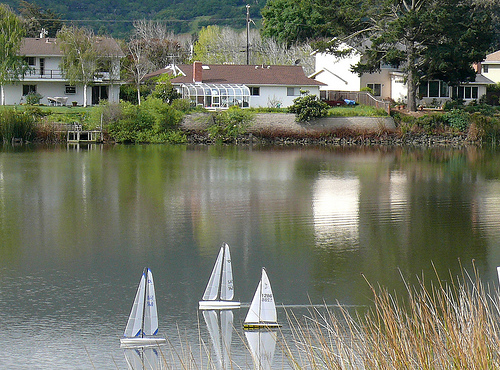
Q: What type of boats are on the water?
A: Sailboats.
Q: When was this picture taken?
A: During the day.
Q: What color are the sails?
A: White.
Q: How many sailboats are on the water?
A: Three.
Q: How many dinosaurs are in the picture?
A: Zero.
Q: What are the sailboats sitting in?
A: Water.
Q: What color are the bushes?
A: Green.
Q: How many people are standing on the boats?
A: Zero.